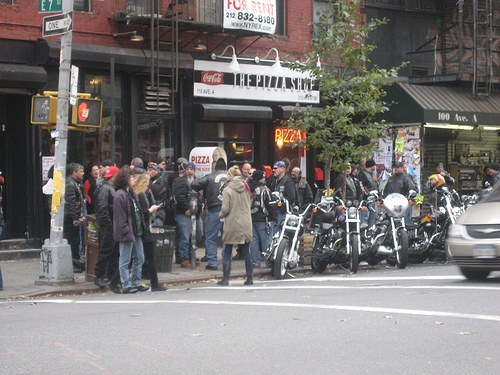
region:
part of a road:
[280, 327, 308, 363]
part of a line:
[341, 270, 386, 335]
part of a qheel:
[376, 241, 400, 274]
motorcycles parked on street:
[268, 174, 460, 276]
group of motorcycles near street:
[271, 172, 451, 281]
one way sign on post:
[33, 7, 78, 43]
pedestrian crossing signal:
[26, 84, 104, 137]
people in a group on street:
[78, 150, 424, 277]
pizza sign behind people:
[181, 140, 232, 186]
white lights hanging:
[214, 40, 327, 82]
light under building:
[428, 119, 498, 136]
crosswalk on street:
[140, 268, 497, 331]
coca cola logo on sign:
[200, 67, 225, 92]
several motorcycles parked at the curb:
[263, 179, 473, 279]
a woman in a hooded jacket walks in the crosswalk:
[216, 163, 258, 293]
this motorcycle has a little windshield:
[364, 187, 418, 267]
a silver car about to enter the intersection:
[441, 168, 498, 288]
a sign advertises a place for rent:
[216, 0, 287, 36]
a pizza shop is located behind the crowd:
[191, 45, 326, 205]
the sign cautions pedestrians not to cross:
[68, 93, 105, 130]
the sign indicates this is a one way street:
[36, 10, 77, 37]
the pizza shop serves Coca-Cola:
[196, 65, 227, 87]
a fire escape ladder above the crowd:
[143, 0, 188, 124]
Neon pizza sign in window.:
[270, 125, 306, 146]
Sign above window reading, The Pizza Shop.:
[160, 58, 321, 102]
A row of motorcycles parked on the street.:
[237, 186, 479, 272]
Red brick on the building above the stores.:
[0, 0, 380, 68]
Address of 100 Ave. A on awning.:
[415, 103, 487, 128]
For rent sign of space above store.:
[204, 0, 284, 41]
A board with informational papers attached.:
[327, 110, 426, 192]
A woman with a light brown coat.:
[191, 157, 262, 291]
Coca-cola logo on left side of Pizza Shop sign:
[190, 65, 225, 87]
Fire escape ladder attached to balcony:
[128, 8, 184, 116]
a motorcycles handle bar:
[265, 190, 330, 217]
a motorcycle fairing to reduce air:
[380, 190, 405, 215]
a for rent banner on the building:
[220, 0, 275, 30]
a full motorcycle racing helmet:
[425, 170, 445, 185]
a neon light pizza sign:
[271, 125, 301, 142]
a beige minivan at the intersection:
[445, 175, 495, 265]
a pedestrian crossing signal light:
[28, 92, 101, 128]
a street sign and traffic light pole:
[33, 0, 93, 289]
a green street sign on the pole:
[38, 0, 89, 11]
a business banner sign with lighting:
[191, 43, 320, 104]